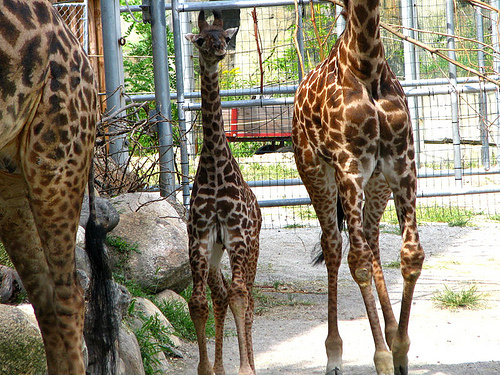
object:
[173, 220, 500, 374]
ground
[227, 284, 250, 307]
knee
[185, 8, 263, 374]
giraffe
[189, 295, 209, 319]
knee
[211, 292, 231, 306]
knee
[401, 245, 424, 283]
knee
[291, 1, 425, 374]
giraffe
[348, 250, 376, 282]
knee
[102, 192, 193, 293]
stone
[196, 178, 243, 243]
chest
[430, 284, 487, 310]
grass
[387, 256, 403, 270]
grass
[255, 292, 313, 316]
grass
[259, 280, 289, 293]
grass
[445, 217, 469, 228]
grass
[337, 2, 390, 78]
neck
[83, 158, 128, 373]
tail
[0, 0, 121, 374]
giraffe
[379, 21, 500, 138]
branch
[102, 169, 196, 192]
branch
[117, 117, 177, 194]
branch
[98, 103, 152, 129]
branch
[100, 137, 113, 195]
branch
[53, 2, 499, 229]
fence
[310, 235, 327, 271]
tail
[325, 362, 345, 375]
hoof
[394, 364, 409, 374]
hoof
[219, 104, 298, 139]
crate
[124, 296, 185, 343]
rock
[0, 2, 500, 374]
enclosure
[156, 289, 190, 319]
rock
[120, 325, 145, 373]
rock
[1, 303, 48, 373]
rock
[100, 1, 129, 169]
pole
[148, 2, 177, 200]
pole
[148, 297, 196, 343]
vegetation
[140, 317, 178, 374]
vegetation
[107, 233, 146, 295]
vegetation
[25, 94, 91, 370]
leg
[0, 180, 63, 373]
leg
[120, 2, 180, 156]
tree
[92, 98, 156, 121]
branches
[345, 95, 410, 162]
chest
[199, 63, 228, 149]
neck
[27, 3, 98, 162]
hip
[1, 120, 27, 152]
stomach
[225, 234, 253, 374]
leg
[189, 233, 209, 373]
leg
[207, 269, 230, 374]
leg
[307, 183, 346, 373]
leg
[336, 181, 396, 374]
leg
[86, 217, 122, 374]
hair